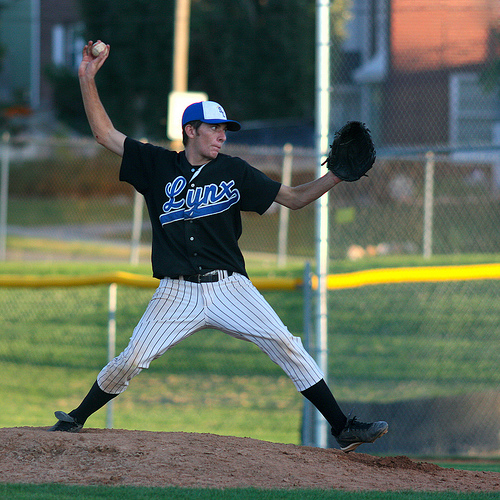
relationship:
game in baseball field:
[35, 26, 399, 462] [1, 428, 499, 498]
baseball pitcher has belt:
[52, 21, 417, 383] [160, 263, 239, 283]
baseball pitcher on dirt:
[54, 40, 386, 459] [0, 421, 498, 498]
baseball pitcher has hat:
[54, 40, 386, 459] [176, 99, 238, 133]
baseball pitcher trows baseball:
[54, 40, 386, 459] [91, 42, 108, 57]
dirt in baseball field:
[0, 420, 498, 490] [0, 428, 498, 500]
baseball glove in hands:
[327, 121, 378, 182] [296, 146, 386, 207]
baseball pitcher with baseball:
[54, 40, 386, 459] [90, 42, 105, 55]